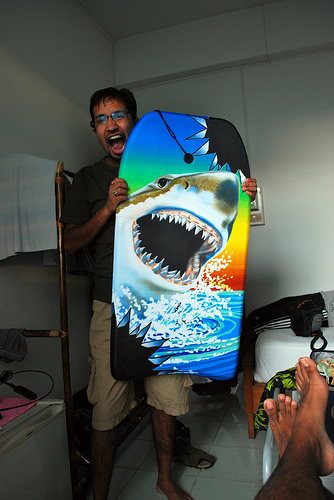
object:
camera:
[289, 301, 322, 337]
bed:
[242, 272, 333, 437]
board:
[109, 109, 252, 382]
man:
[60, 85, 257, 498]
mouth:
[106, 134, 129, 158]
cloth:
[0, 155, 57, 263]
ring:
[113, 191, 116, 196]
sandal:
[175, 443, 216, 470]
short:
[87, 296, 138, 433]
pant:
[86, 286, 192, 432]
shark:
[113, 172, 239, 294]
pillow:
[253, 366, 324, 433]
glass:
[90, 110, 128, 125]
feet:
[295, 356, 333, 477]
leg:
[89, 301, 123, 499]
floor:
[86, 352, 263, 498]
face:
[95, 103, 132, 156]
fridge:
[0, 399, 71, 498]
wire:
[0, 369, 54, 400]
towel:
[0, 152, 57, 263]